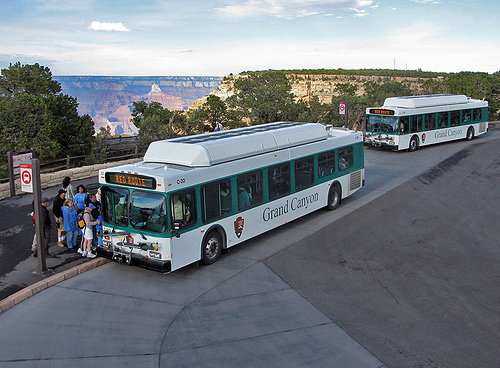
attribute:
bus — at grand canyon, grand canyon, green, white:
[86, 118, 370, 276]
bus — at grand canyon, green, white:
[361, 92, 494, 154]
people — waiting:
[28, 173, 105, 257]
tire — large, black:
[198, 229, 226, 266]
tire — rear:
[326, 182, 344, 211]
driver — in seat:
[157, 193, 195, 229]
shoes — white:
[87, 251, 96, 261]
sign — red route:
[103, 172, 160, 189]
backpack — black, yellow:
[75, 213, 88, 231]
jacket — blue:
[59, 205, 80, 232]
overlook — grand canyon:
[3, 128, 384, 179]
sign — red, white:
[19, 160, 33, 193]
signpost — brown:
[28, 157, 48, 272]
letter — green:
[263, 205, 273, 223]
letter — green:
[270, 208, 274, 220]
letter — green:
[273, 205, 278, 219]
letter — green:
[278, 206, 283, 216]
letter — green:
[285, 196, 289, 217]